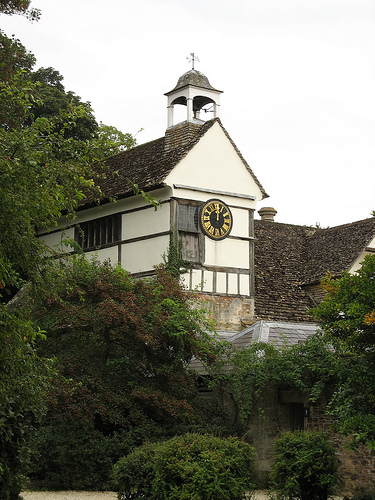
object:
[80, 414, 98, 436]
leaves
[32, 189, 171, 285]
wall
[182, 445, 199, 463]
leaves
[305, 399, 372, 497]
wall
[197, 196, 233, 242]
clock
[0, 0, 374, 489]
trees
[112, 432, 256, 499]
bush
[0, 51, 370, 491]
building